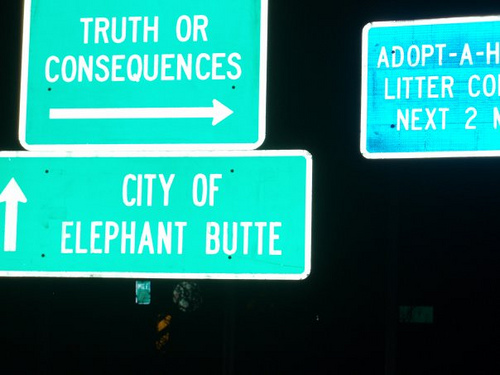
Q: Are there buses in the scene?
A: No, there are no buses.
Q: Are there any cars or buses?
A: No, there are no buses or cars.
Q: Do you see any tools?
A: No, there are no tools.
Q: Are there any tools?
A: No, there are no tools.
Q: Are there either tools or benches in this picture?
A: No, there are no tools or benches.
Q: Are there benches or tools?
A: No, there are no tools or benches.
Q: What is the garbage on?
A: The garbage is on the sign.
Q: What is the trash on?
A: The garbage is on the sign.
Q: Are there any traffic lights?
A: No, there are no traffic lights.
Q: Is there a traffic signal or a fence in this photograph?
A: No, there are no traffic lights or fences.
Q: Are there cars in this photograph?
A: No, there are no cars.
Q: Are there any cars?
A: No, there are no cars.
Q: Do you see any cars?
A: No, there are no cars.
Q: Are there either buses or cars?
A: No, there are no cars or buses.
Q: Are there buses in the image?
A: No, there are no buses.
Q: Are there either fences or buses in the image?
A: No, there are no buses or fences.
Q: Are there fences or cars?
A: No, there are no cars or fences.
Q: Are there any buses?
A: No, there are no buses.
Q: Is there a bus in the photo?
A: No, there are no buses.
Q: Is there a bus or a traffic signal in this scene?
A: No, there are no buses or traffic lights.